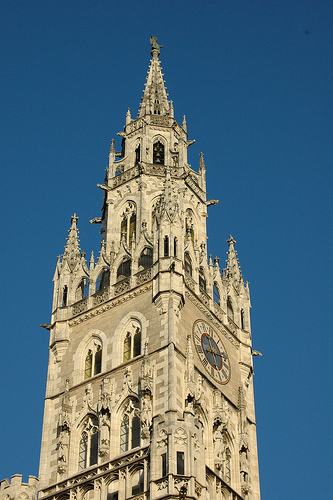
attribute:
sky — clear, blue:
[0, 1, 332, 500]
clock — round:
[192, 318, 230, 385]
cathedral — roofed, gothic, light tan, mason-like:
[2, 34, 263, 500]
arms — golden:
[205, 337, 224, 371]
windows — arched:
[78, 325, 142, 476]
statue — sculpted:
[149, 35, 163, 51]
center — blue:
[201, 334, 222, 370]